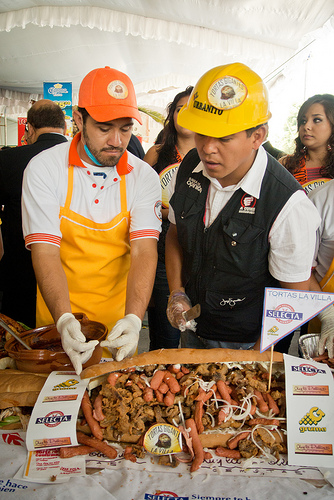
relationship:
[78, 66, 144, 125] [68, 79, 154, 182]
cap orange baseball cap on someones head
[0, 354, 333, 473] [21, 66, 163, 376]
food under man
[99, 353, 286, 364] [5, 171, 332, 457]
brown food in photo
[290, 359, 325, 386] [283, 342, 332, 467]
design on paper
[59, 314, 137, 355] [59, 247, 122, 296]
gloves on persons hand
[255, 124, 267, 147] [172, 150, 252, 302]
ear of man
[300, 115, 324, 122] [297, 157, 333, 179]
eyes of girl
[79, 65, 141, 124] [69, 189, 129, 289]
orange hat on man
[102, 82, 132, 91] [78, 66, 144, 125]
logo on cap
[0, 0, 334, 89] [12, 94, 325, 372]
ceiling in photo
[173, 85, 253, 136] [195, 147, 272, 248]
hat on man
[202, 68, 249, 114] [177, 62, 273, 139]
sticker on hat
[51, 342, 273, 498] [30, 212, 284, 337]
food under people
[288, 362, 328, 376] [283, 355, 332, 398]
writing on paper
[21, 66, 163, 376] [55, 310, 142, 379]
man has hands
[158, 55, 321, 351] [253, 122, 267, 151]
man has ear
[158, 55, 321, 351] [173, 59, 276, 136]
man wears hat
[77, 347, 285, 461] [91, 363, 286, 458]
sub has beef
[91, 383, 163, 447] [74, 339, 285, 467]
beef in sub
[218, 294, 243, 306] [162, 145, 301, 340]
signature on apron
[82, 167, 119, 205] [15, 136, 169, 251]
button on shirt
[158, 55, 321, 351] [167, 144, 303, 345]
man wears vest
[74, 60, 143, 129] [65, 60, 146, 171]
cap on head